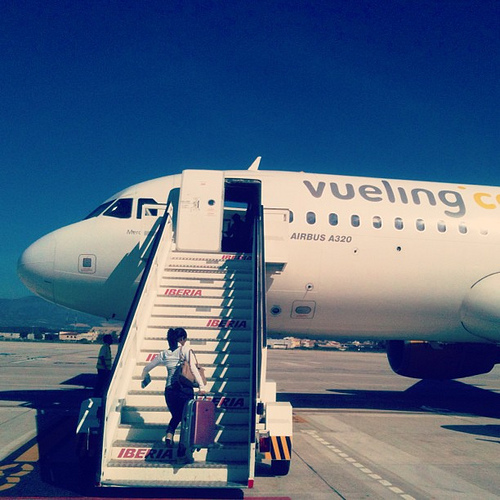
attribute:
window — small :
[306, 212, 316, 224]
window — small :
[329, 214, 338, 226]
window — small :
[351, 215, 359, 226]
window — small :
[372, 216, 382, 229]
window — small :
[394, 218, 403, 230]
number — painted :
[0, 455, 32, 493]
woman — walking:
[140, 319, 218, 465]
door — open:
[169, 159, 266, 263]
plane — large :
[18, 164, 498, 381]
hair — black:
[163, 323, 188, 352]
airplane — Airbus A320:
[76, 150, 410, 324]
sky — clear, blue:
[1, 1, 499, 301]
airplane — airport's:
[2, 181, 494, 459]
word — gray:
[304, 176, 498, 217]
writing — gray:
[309, 181, 464, 208]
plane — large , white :
[12, 151, 490, 494]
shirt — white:
[144, 350, 204, 386]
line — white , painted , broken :
[305, 427, 431, 497]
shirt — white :
[142, 342, 205, 391]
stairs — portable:
[140, 353, 230, 485]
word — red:
[162, 284, 207, 300]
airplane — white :
[16, 155, 497, 485]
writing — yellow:
[463, 184, 496, 212]